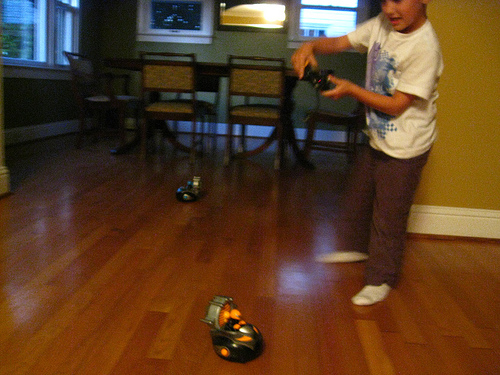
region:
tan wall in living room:
[447, 15, 492, 196]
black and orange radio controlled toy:
[179, 275, 282, 372]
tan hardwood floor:
[18, 213, 173, 344]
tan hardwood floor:
[220, 195, 318, 292]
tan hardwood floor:
[416, 253, 490, 364]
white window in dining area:
[13, 5, 87, 78]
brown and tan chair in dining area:
[120, 34, 227, 167]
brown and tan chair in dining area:
[220, 46, 305, 184]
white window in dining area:
[122, 4, 227, 53]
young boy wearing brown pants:
[322, 115, 436, 292]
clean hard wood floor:
[106, 207, 295, 267]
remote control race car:
[202, 295, 271, 358]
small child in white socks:
[321, 245, 390, 310]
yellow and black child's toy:
[203, 302, 267, 366]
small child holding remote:
[301, 50, 346, 102]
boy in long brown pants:
[356, 132, 416, 289]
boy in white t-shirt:
[343, 25, 440, 161]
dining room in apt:
[76, 45, 348, 177]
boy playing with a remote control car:
[161, 16, 471, 368]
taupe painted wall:
[449, 100, 498, 196]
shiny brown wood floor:
[108, 214, 235, 246]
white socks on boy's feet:
[342, 277, 407, 304]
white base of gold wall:
[431, 181, 471, 264]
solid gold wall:
[460, 60, 480, 140]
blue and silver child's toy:
[159, 168, 230, 218]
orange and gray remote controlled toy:
[177, 277, 277, 366]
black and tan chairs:
[215, 37, 315, 176]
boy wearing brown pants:
[329, 129, 441, 263]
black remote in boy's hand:
[295, 57, 343, 112]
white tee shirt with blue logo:
[354, 29, 464, 174]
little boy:
[344, 0, 434, 318]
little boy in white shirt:
[370, 11, 459, 343]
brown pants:
[365, 127, 414, 307]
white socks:
[357, 283, 396, 320]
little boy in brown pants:
[352, 11, 444, 288]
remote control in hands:
[282, 40, 378, 143]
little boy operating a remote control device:
[187, 13, 436, 368]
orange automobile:
[213, 306, 272, 362]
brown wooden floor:
[31, 213, 144, 371]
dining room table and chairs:
[149, 48, 296, 134]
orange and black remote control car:
[199, 276, 276, 373]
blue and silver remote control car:
[170, 162, 213, 205]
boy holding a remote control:
[290, 0, 451, 174]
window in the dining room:
[1, 0, 86, 85]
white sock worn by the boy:
[347, 265, 404, 327]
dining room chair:
[132, 32, 219, 163]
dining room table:
[100, 31, 300, 148]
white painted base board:
[414, 195, 496, 252]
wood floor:
[30, 161, 168, 365]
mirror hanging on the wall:
[213, 1, 291, 38]